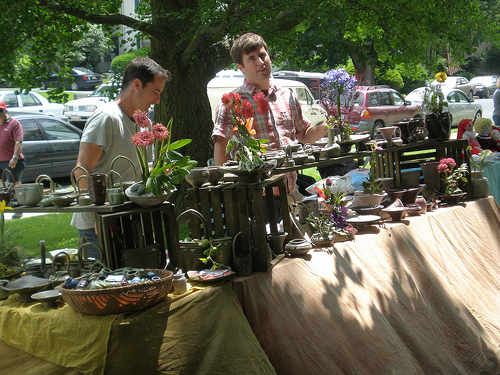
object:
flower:
[318, 63, 363, 138]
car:
[0, 87, 64, 119]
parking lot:
[0, 72, 120, 182]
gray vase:
[14, 182, 46, 206]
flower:
[132, 109, 160, 145]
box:
[96, 202, 183, 273]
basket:
[57, 261, 174, 318]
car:
[321, 73, 417, 140]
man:
[72, 53, 170, 227]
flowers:
[121, 107, 178, 169]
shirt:
[83, 107, 165, 229]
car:
[410, 83, 484, 124]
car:
[8, 108, 85, 183]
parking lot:
[2, 68, 497, 189]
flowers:
[201, 88, 398, 168]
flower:
[219, 93, 266, 144]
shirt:
[206, 82, 306, 183]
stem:
[335, 114, 351, 151]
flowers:
[324, 80, 331, 85]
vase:
[283, 237, 313, 256]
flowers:
[225, 88, 259, 163]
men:
[69, 34, 331, 259]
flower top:
[130, 107, 157, 129]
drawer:
[93, 209, 186, 256]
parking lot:
[310, 79, 498, 129]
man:
[206, 30, 330, 230]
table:
[15, 190, 478, 367]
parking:
[326, 57, 416, 134]